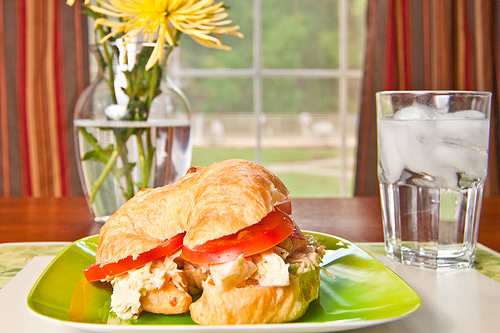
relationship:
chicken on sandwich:
[113, 267, 174, 317] [103, 175, 314, 314]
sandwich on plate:
[103, 175, 314, 314] [59, 233, 415, 332]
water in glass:
[388, 119, 481, 249] [371, 78, 483, 265]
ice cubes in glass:
[385, 109, 479, 182] [371, 78, 483, 265]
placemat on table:
[1, 235, 499, 329] [2, 189, 472, 332]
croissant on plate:
[118, 171, 261, 237] [59, 233, 415, 332]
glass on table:
[371, 78, 483, 265] [2, 189, 472, 332]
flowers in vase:
[94, 1, 235, 54] [66, 50, 197, 212]